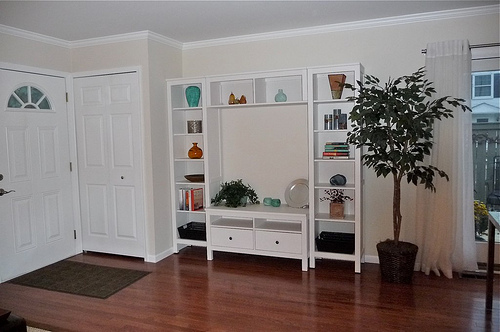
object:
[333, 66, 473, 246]
tree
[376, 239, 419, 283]
basket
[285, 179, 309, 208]
plate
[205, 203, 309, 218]
shelf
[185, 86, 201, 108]
vase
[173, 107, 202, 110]
shelf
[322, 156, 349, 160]
books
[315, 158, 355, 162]
shelf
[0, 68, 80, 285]
door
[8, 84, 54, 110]
window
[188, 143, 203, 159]
vase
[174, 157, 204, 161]
shelf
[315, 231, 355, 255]
basket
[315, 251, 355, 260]
shelf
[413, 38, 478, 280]
curtains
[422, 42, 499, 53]
rod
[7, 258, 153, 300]
rug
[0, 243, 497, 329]
floors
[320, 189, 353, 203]
plant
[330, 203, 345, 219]
vase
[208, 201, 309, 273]
cabinets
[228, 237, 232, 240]
knobs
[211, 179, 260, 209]
plant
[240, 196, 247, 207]
pot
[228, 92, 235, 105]
pears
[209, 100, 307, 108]
shelf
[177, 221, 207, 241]
basket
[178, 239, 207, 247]
shelf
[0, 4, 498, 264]
walls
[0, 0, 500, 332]
room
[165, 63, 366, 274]
shelves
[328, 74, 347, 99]
pot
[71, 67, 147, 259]
door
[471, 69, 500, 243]
window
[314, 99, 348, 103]
shelf